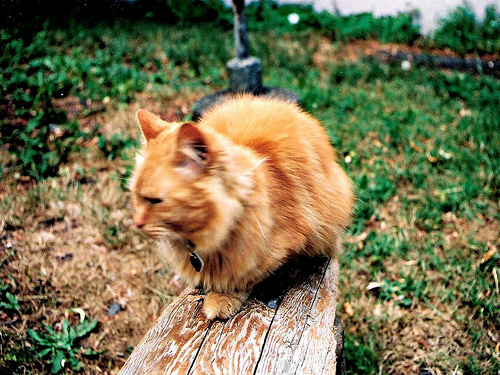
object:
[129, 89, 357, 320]
cat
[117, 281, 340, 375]
log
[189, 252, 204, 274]
tag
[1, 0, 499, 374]
ground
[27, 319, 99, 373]
weed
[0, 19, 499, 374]
grass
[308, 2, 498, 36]
sky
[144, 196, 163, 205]
eye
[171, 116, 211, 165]
ears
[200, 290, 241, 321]
foot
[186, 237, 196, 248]
collar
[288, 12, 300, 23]
bloom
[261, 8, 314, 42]
plant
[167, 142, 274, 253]
neck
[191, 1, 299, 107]
stand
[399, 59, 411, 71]
ball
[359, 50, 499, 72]
log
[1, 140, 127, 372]
patch